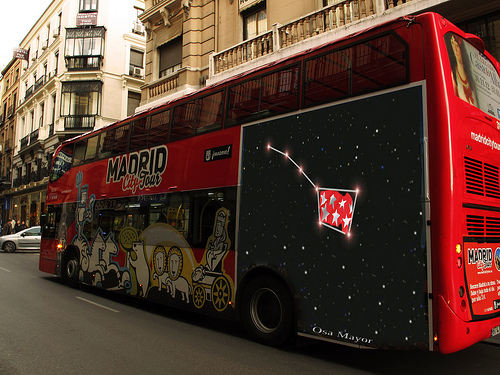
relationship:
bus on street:
[58, 94, 215, 303] [30, 292, 79, 321]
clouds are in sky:
[11, 19, 24, 27] [21, 1, 33, 7]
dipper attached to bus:
[254, 137, 352, 233] [58, 94, 215, 303]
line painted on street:
[92, 303, 109, 310] [30, 292, 79, 321]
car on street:
[8, 231, 33, 253] [30, 292, 79, 321]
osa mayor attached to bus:
[132, 240, 191, 282] [58, 94, 215, 303]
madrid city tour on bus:
[82, 144, 169, 190] [58, 94, 215, 303]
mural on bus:
[305, 129, 362, 173] [58, 94, 215, 303]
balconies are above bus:
[228, 15, 302, 49] [58, 94, 215, 303]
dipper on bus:
[254, 137, 352, 233] [58, 94, 215, 303]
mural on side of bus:
[305, 129, 362, 173] [58, 94, 215, 303]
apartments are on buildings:
[44, 5, 93, 45] [42, 7, 237, 60]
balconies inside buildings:
[228, 15, 302, 49] [42, 7, 237, 60]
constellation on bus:
[321, 268, 371, 289] [58, 94, 215, 303]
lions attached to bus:
[144, 248, 176, 282] [58, 94, 215, 303]